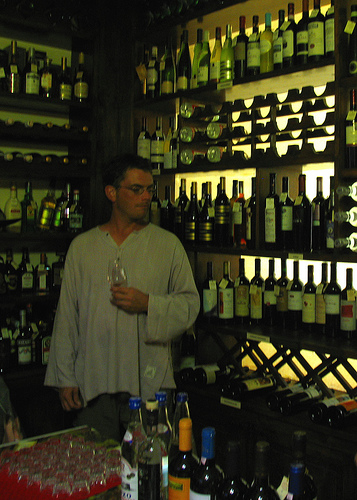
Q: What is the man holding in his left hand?
A: A wine glass.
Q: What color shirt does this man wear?
A: White.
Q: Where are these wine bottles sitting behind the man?
A: On shelves.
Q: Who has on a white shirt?
A: A man.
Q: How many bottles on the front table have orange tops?
A: One.